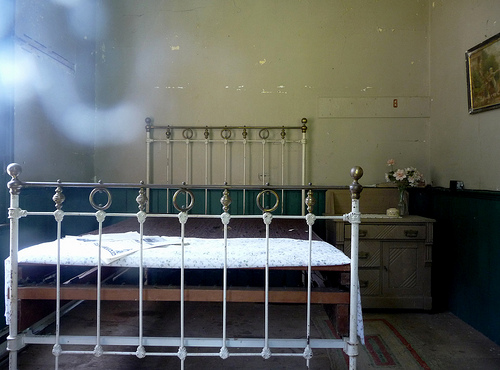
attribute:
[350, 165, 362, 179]
knob — brass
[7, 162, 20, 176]
knob — brass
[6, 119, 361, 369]
bed — iron-framed, old, iron, metal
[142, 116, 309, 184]
headboard — metal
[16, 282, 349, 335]
stand — wooden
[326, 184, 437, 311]
stand — bed side, small, wooden, brown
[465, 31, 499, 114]
painting — framed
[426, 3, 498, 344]
wall — white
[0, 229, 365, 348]
sheet — white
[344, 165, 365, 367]
bedpost — brass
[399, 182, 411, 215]
bottle — small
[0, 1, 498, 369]
bedroom — old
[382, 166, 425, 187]
flowers — white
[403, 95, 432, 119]
tile — green, white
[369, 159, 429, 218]
flower — flower wash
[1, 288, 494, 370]
floor — mate